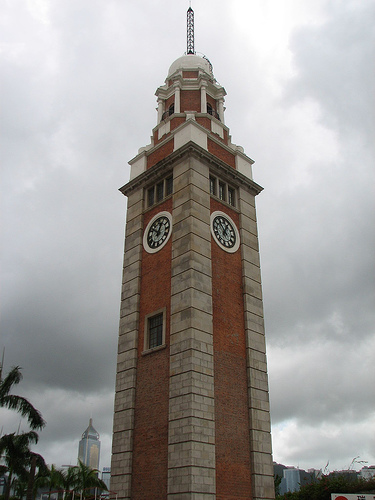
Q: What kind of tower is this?
A: Clock tower.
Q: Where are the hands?
A: On clock.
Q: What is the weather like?
A: Cloudy.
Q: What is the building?
A: Tall.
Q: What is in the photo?
A: The tower.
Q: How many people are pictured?
A: None.